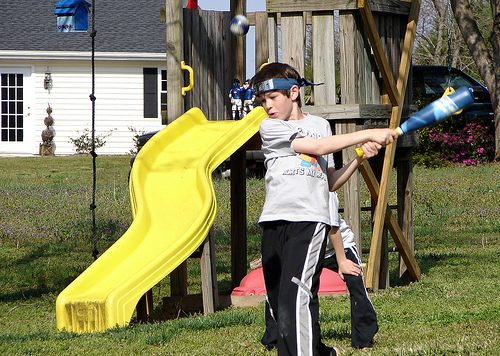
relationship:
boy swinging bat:
[250, 61, 402, 355] [355, 85, 474, 160]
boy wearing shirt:
[250, 61, 402, 355] [256, 112, 336, 227]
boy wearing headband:
[250, 61, 402, 355] [251, 76, 325, 94]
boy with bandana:
[250, 61, 402, 355] [251, 76, 325, 94]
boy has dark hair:
[250, 61, 402, 355] [248, 61, 302, 109]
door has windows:
[1, 63, 37, 160] [2, 73, 23, 141]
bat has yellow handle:
[355, 85, 474, 160] [353, 127, 404, 158]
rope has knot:
[86, 1, 104, 262] [87, 25, 101, 40]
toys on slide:
[225, 78, 256, 122] [52, 105, 271, 328]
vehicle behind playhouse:
[413, 59, 499, 133] [263, 1, 423, 293]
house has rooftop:
[1, 1, 170, 159] [1, 1, 168, 54]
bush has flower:
[417, 119, 497, 173] [475, 146, 485, 157]